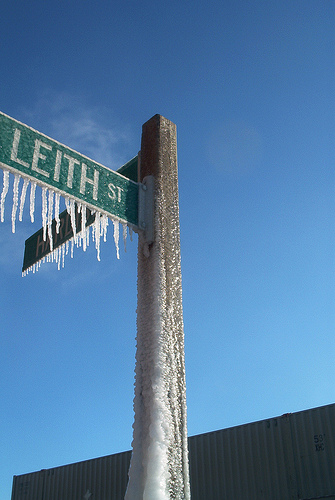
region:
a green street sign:
[0, 103, 149, 237]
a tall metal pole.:
[120, 100, 186, 490]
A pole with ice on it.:
[129, 101, 191, 496]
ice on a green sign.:
[0, 167, 133, 266]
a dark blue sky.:
[2, 1, 334, 495]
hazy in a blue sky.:
[34, 73, 221, 207]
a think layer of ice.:
[152, 100, 204, 495]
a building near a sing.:
[11, 404, 333, 497]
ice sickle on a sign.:
[0, 164, 134, 271]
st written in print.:
[102, 178, 130, 204]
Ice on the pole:
[125, 252, 187, 496]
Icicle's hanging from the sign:
[1, 173, 131, 258]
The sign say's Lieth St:
[6, 113, 139, 235]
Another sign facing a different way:
[9, 201, 115, 272]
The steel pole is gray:
[130, 99, 188, 496]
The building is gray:
[198, 406, 325, 498]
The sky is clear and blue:
[41, 12, 318, 75]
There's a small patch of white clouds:
[16, 83, 136, 170]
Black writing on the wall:
[311, 428, 330, 456]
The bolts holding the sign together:
[132, 177, 150, 231]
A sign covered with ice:
[0, 116, 151, 214]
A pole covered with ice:
[118, 299, 190, 493]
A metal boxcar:
[214, 411, 329, 494]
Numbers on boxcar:
[302, 421, 324, 474]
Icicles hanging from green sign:
[2, 191, 142, 255]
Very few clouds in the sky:
[32, 58, 196, 178]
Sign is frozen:
[0, 168, 96, 216]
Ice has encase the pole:
[129, 271, 189, 498]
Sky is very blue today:
[213, 219, 306, 304]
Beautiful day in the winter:
[8, 333, 266, 452]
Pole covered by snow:
[140, 112, 187, 499]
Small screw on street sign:
[140, 219, 147, 228]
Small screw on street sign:
[140, 181, 148, 189]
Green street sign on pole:
[0, 110, 144, 228]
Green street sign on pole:
[21, 151, 138, 272]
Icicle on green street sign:
[113, 217, 121, 258]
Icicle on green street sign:
[93, 209, 102, 261]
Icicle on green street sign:
[80, 199, 87, 243]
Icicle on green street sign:
[53, 192, 63, 234]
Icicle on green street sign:
[39, 187, 48, 241]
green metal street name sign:
[0, 96, 141, 201]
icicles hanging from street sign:
[0, 176, 134, 256]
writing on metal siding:
[303, 424, 327, 454]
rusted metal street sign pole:
[119, 94, 216, 172]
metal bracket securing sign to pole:
[133, 175, 156, 244]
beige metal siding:
[201, 415, 273, 497]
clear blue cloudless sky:
[165, 4, 332, 103]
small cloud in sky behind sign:
[68, 115, 131, 146]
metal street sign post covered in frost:
[114, 305, 206, 497]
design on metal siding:
[74, 485, 100, 497]